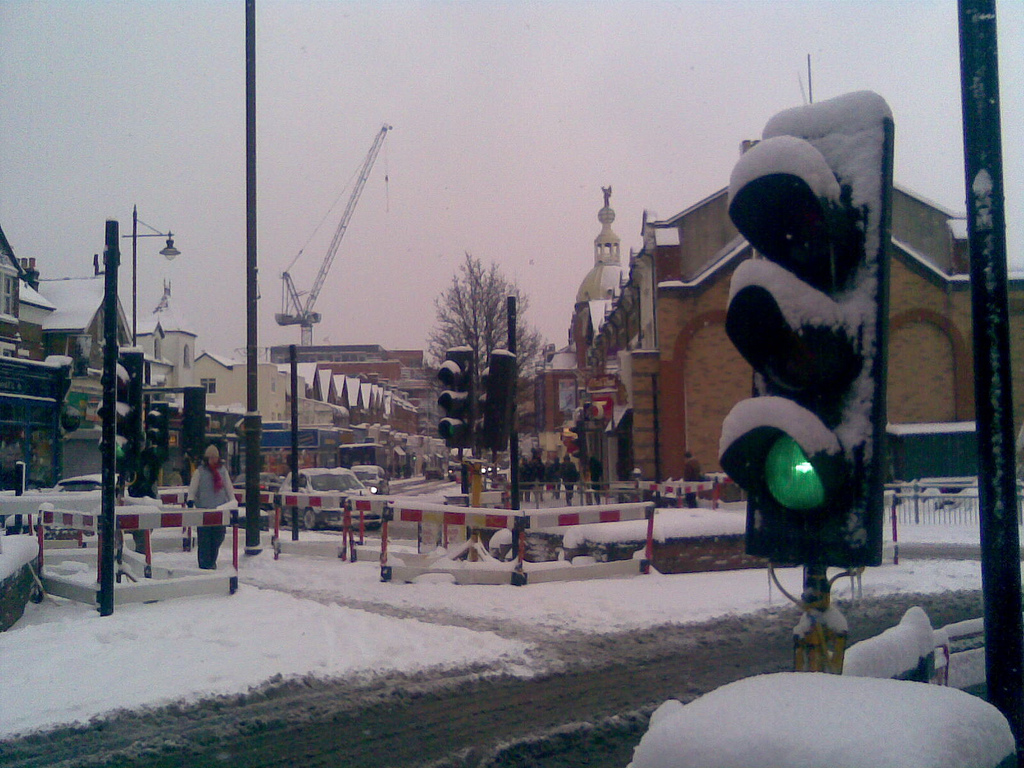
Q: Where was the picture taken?
A: It was taken at the sidewalk.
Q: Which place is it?
A: It is a sidewalk.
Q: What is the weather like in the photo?
A: It is overcast.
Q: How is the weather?
A: It is overcast.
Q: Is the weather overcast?
A: Yes, it is overcast.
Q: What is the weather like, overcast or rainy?
A: It is overcast.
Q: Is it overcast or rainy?
A: It is overcast.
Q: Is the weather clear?
A: No, it is overcast.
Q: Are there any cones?
A: No, there are no cones.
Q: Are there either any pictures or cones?
A: No, there are no cones or pictures.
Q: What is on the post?
A: The street lamp is on the post.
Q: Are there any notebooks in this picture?
A: No, there are no notebooks.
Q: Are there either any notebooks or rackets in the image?
A: No, there are no notebooks or rackets.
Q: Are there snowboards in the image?
A: No, there are no snowboards.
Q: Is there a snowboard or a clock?
A: No, there are no snowboards or clocks.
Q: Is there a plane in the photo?
A: No, there are no airplanes.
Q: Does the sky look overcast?
A: Yes, the sky is overcast.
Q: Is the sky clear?
A: No, the sky is overcast.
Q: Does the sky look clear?
A: No, the sky is overcast.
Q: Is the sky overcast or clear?
A: The sky is overcast.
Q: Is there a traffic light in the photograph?
A: Yes, there is a traffic light.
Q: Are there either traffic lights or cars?
A: Yes, there is a traffic light.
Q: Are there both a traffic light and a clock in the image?
A: No, there is a traffic light but no clocks.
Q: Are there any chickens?
A: No, there are no chickens.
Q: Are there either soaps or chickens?
A: No, there are no chickens or soaps.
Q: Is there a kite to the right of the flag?
A: No, there is a traffic light to the right of the flag.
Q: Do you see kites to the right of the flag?
A: No, there is a traffic light to the right of the flag.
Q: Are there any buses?
A: Yes, there is a bus.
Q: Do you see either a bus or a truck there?
A: Yes, there is a bus.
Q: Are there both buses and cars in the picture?
A: Yes, there are both a bus and a car.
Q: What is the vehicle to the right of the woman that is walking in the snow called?
A: The vehicle is a bus.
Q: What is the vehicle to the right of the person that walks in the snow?
A: The vehicle is a bus.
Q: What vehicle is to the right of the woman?
A: The vehicle is a bus.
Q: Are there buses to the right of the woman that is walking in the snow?
A: Yes, there is a bus to the right of the woman.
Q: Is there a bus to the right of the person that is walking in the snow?
A: Yes, there is a bus to the right of the woman.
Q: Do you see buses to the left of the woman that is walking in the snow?
A: No, the bus is to the right of the woman.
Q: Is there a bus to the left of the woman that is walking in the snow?
A: No, the bus is to the right of the woman.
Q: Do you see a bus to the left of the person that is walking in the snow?
A: No, the bus is to the right of the woman.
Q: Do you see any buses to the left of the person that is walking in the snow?
A: No, the bus is to the right of the woman.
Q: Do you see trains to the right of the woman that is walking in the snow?
A: No, there is a bus to the right of the woman.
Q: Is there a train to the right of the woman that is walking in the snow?
A: No, there is a bus to the right of the woman.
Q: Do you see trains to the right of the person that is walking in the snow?
A: No, there is a bus to the right of the woman.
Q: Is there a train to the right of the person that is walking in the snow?
A: No, there is a bus to the right of the woman.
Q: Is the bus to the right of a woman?
A: Yes, the bus is to the right of a woman.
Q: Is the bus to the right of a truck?
A: No, the bus is to the right of a woman.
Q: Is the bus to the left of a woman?
A: No, the bus is to the right of a woman.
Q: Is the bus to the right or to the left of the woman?
A: The bus is to the right of the woman.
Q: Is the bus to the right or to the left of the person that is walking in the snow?
A: The bus is to the right of the woman.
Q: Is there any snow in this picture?
A: Yes, there is snow.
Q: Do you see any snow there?
A: Yes, there is snow.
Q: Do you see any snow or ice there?
A: Yes, there is snow.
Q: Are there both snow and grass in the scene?
A: No, there is snow but no grass.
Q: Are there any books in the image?
A: No, there are no books.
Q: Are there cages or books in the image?
A: No, there are no books or cages.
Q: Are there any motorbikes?
A: No, there are no motorbikes.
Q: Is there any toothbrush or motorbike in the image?
A: No, there are no motorcycles or toothbrushes.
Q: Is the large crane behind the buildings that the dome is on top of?
A: Yes, the crane is behind the buildings.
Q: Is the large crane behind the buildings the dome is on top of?
A: Yes, the crane is behind the buildings.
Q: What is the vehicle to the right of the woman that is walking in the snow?
A: The vehicle is a car.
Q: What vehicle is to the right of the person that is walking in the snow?
A: The vehicle is a car.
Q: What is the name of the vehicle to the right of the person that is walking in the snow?
A: The vehicle is a car.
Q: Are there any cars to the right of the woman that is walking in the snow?
A: Yes, there is a car to the right of the woman.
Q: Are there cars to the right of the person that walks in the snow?
A: Yes, there is a car to the right of the woman.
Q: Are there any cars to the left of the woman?
A: No, the car is to the right of the woman.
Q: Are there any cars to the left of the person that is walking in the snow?
A: No, the car is to the right of the woman.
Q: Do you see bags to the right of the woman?
A: No, there is a car to the right of the woman.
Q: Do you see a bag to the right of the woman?
A: No, there is a car to the right of the woman.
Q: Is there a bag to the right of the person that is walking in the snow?
A: No, there is a car to the right of the woman.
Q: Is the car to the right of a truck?
A: No, the car is to the right of the woman.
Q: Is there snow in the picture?
A: Yes, there is snow.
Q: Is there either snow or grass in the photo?
A: Yes, there is snow.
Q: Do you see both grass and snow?
A: No, there is snow but no grass.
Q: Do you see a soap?
A: No, there are no soaps.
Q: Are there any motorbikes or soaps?
A: No, there are no soaps or motorbikes.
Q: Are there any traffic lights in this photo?
A: Yes, there is a traffic light.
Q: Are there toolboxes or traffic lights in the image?
A: Yes, there is a traffic light.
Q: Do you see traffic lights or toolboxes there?
A: Yes, there is a traffic light.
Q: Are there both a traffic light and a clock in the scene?
A: No, there is a traffic light but no clocks.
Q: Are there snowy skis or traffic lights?
A: Yes, there is a snowy traffic light.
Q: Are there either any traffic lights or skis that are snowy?
A: Yes, the traffic light is snowy.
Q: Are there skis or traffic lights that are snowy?
A: Yes, the traffic light is snowy.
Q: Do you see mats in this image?
A: No, there are no mats.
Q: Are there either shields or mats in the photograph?
A: No, there are no mats or shields.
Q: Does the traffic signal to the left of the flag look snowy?
A: Yes, the traffic signal is snowy.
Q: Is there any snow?
A: Yes, there is snow.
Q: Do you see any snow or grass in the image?
A: Yes, there is snow.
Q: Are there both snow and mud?
A: No, there is snow but no mud.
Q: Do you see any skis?
A: No, there are no skis.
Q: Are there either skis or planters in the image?
A: No, there are no skis or planters.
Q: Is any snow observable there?
A: Yes, there is snow.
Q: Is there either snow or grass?
A: Yes, there is snow.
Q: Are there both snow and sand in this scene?
A: No, there is snow but no sand.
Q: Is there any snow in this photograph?
A: Yes, there is snow.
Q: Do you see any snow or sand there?
A: Yes, there is snow.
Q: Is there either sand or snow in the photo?
A: Yes, there is snow.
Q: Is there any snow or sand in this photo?
A: Yes, there is snow.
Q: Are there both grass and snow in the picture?
A: No, there is snow but no grass.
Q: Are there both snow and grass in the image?
A: No, there is snow but no grass.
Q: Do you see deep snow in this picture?
A: Yes, there is deep snow.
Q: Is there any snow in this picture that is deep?
A: Yes, there is snow that is deep.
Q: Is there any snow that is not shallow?
A: Yes, there is deep snow.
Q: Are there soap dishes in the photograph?
A: No, there are no soap dishes.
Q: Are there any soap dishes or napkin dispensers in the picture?
A: No, there are no soap dishes or napkin dispensers.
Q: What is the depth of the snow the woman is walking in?
A: The snow is deep.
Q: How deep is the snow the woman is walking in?
A: The snow is deep.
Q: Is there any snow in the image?
A: Yes, there is snow.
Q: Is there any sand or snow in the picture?
A: Yes, there is snow.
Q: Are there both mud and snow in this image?
A: No, there is snow but no mud.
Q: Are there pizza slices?
A: No, there are no pizza slices.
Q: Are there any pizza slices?
A: No, there are no pizza slices.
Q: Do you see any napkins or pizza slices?
A: No, there are no pizza slices or napkins.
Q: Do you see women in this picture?
A: Yes, there is a woman.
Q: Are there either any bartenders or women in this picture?
A: Yes, there is a woman.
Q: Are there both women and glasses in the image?
A: No, there is a woman but no glasses.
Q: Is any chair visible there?
A: No, there are no chairs.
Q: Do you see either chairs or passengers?
A: No, there are no chairs or passengers.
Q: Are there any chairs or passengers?
A: No, there are no chairs or passengers.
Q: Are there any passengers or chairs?
A: No, there are no chairs or passengers.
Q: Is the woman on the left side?
A: Yes, the woman is on the left of the image.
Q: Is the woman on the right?
A: No, the woman is on the left of the image.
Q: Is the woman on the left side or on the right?
A: The woman is on the left of the image.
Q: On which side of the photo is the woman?
A: The woman is on the left of the image.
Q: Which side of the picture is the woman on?
A: The woman is on the left of the image.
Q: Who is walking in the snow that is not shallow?
A: The woman is walking in the snow.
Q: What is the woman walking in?
A: The woman is walking in the snow.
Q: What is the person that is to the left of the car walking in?
A: The woman is walking in the snow.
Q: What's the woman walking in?
A: The woman is walking in the snow.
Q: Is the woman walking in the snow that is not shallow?
A: Yes, the woman is walking in the snow.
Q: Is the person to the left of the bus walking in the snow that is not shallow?
A: Yes, the woman is walking in the snow.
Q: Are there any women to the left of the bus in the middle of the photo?
A: Yes, there is a woman to the left of the bus.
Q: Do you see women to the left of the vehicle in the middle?
A: Yes, there is a woman to the left of the bus.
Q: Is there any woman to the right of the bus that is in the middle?
A: No, the woman is to the left of the bus.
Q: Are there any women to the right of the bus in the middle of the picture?
A: No, the woman is to the left of the bus.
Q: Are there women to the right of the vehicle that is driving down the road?
A: No, the woman is to the left of the bus.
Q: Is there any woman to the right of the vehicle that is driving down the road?
A: No, the woman is to the left of the bus.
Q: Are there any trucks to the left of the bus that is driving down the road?
A: No, there is a woman to the left of the bus.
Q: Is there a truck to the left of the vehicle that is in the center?
A: No, there is a woman to the left of the bus.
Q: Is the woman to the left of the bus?
A: Yes, the woman is to the left of the bus.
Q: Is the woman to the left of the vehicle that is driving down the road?
A: Yes, the woman is to the left of the bus.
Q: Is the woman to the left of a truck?
A: No, the woman is to the left of the bus.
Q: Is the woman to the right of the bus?
A: No, the woman is to the left of the bus.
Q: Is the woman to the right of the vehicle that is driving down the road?
A: No, the woman is to the left of the bus.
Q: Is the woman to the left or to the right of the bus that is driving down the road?
A: The woman is to the left of the bus.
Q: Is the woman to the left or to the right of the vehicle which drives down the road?
A: The woman is to the left of the bus.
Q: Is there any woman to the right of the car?
A: No, the woman is to the left of the car.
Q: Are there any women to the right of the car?
A: No, the woman is to the left of the car.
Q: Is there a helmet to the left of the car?
A: No, there is a woman to the left of the car.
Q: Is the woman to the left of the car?
A: Yes, the woman is to the left of the car.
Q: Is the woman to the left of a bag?
A: No, the woman is to the left of the car.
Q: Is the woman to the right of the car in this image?
A: No, the woman is to the left of the car.